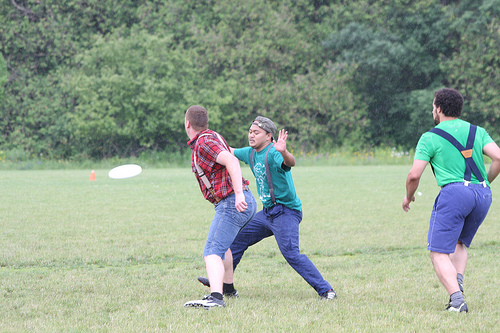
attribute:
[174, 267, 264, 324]
shoes — white, black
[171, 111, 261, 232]
man — playing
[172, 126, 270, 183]
shirt — plaid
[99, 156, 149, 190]
disc — white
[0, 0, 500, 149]
bush — green, thick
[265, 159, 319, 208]
shirt — green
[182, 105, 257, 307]
man — playing, standing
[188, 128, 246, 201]
plaid shirt — red, black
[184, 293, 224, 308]
shoes — black, white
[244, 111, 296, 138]
cap — gray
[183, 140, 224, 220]
suspenders — gray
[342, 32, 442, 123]
bush — green, thick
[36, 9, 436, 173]
trees — leafy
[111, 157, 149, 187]
frisbee — white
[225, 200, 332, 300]
jeans — blue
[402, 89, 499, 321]
man — big fat, playing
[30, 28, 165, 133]
bush — thick, green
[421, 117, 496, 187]
suspenders — blue, criss crossed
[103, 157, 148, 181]
frisbee — white, flying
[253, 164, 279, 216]
design — white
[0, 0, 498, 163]
trees — leafy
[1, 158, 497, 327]
field — grassy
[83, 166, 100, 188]
cone — orange, short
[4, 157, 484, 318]
grass — green, short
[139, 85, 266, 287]
man — big 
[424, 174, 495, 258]
shorts — blue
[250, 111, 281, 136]
hat — gray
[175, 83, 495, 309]
men — playing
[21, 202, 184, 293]
grass — thick, green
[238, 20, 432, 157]
bush — thick, green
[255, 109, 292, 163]
cap — tilted, gray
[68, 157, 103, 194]
cone — orange, short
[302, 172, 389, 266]
grass field — thick, green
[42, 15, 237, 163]
tree — leafy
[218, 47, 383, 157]
tree — leafy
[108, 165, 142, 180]
frisbee — white